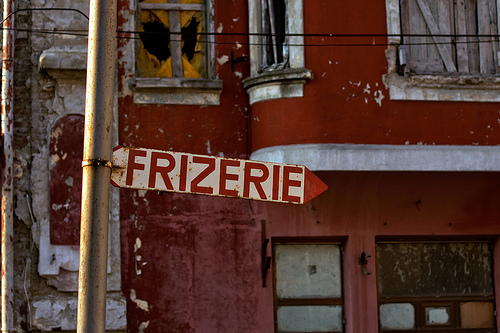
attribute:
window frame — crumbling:
[381, 1, 498, 104]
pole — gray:
[71, 0, 119, 332]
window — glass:
[373, 231, 495, 331]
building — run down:
[4, 2, 496, 332]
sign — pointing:
[105, 141, 329, 209]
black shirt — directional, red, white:
[106, 144, 328, 206]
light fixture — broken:
[354, 246, 376, 278]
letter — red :
[146, 152, 176, 194]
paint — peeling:
[108, 189, 273, 327]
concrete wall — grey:
[120, 2, 497, 330]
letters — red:
[124, 145, 305, 203]